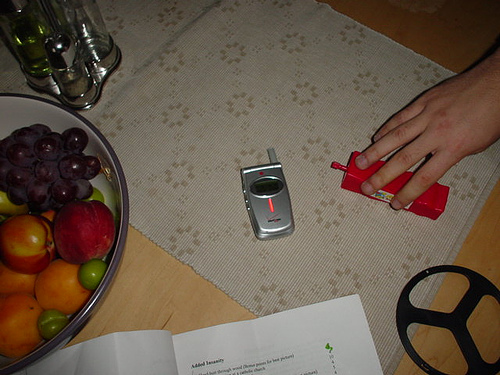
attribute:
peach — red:
[51, 195, 114, 264]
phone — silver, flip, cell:
[230, 140, 309, 242]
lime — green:
[83, 256, 106, 283]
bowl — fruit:
[0, 78, 130, 372]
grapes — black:
[1, 117, 101, 226]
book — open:
[15, 290, 393, 373]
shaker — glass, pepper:
[29, 23, 99, 104]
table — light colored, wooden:
[132, 265, 193, 310]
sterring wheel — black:
[393, 256, 495, 373]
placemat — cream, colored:
[1, 0, 496, 374]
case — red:
[328, 153, 450, 218]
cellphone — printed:
[239, 147, 294, 241]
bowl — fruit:
[0, 90, 124, 367]